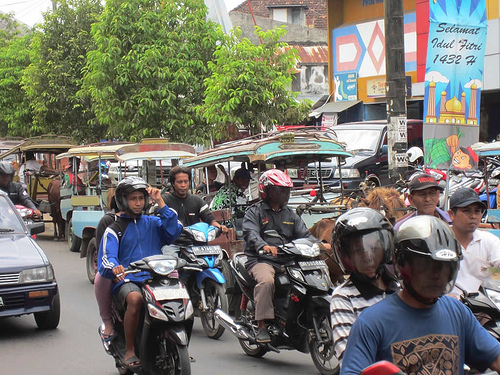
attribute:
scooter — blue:
[184, 219, 229, 337]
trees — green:
[1, 0, 310, 138]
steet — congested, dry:
[0, 212, 499, 374]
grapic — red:
[257, 168, 294, 199]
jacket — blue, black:
[102, 209, 182, 280]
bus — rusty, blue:
[176, 126, 350, 212]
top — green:
[180, 126, 353, 168]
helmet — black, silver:
[390, 211, 466, 296]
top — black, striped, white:
[331, 276, 403, 357]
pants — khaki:
[247, 260, 277, 322]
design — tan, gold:
[391, 335, 458, 373]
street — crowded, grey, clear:
[0, 236, 318, 371]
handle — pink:
[360, 361, 398, 373]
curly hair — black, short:
[168, 165, 192, 182]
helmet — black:
[116, 176, 150, 212]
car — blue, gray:
[0, 192, 60, 327]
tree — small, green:
[196, 25, 313, 130]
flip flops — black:
[116, 351, 143, 370]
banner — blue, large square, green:
[426, 0, 485, 169]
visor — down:
[343, 230, 393, 279]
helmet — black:
[331, 207, 394, 280]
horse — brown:
[47, 175, 71, 242]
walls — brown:
[230, 0, 333, 46]